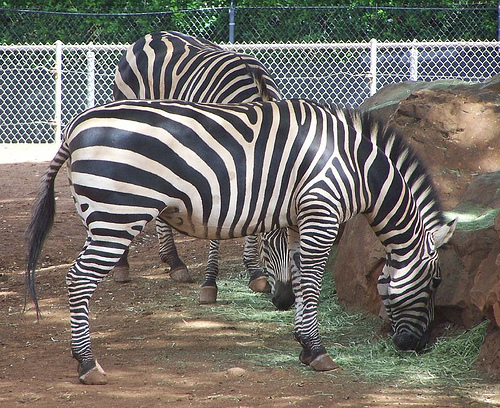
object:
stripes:
[151, 29, 181, 90]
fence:
[0, 0, 499, 166]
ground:
[378, 127, 403, 156]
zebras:
[107, 26, 299, 311]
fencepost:
[225, 4, 239, 44]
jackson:
[385, 301, 433, 354]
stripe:
[73, 104, 215, 125]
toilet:
[0, 0, 499, 407]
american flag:
[284, 100, 461, 372]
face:
[386, 255, 442, 352]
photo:
[0, 0, 500, 407]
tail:
[24, 135, 69, 325]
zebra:
[25, 95, 459, 385]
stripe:
[71, 154, 196, 216]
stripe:
[357, 132, 374, 209]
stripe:
[82, 254, 117, 268]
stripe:
[391, 275, 422, 286]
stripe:
[321, 112, 338, 162]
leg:
[113, 248, 134, 269]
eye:
[432, 275, 443, 288]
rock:
[331, 71, 500, 376]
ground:
[0, 159, 499, 407]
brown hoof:
[197, 285, 219, 305]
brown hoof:
[246, 276, 272, 294]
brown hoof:
[109, 264, 131, 282]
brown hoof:
[167, 265, 197, 284]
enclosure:
[0, 0, 499, 407]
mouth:
[390, 328, 418, 351]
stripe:
[86, 222, 142, 240]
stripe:
[267, 97, 316, 231]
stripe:
[355, 115, 378, 209]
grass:
[166, 246, 498, 393]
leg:
[67, 211, 138, 358]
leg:
[240, 226, 266, 273]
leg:
[203, 231, 223, 286]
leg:
[158, 211, 185, 267]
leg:
[297, 187, 341, 340]